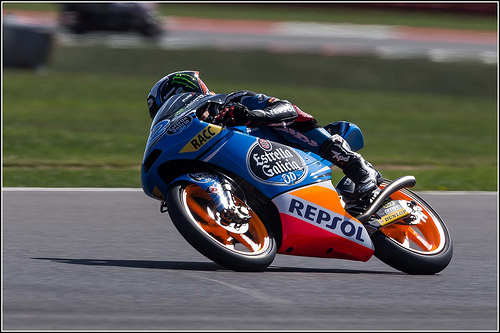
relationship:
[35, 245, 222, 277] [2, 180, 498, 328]
shadow on ground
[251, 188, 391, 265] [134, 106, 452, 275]
ad on motorcycle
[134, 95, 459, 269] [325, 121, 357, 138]
motorcycle has seat